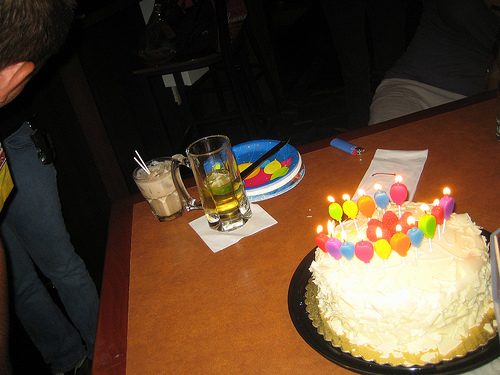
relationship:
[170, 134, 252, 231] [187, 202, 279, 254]
beer on top of napkin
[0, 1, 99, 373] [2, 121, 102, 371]
person wearing jeans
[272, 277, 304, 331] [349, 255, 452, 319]
plate holding cake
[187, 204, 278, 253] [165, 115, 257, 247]
napkin under mug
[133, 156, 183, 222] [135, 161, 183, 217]
cup filled with drink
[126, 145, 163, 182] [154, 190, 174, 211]
straw in glass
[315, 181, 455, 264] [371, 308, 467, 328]
candles on cake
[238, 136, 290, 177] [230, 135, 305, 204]
knife on plates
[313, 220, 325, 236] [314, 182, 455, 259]
flame on candle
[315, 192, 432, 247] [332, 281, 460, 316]
candles on cake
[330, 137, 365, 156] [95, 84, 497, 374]
cigarette lighter on top of table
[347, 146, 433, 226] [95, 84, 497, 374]
paper on top of table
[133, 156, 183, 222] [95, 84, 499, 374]
cup on table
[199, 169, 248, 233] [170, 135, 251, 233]
beer in glass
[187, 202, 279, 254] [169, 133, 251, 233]
napkin under mug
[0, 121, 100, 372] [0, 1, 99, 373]
jeans on person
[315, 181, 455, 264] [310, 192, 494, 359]
candles on top of cake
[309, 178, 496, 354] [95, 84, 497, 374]
cake on table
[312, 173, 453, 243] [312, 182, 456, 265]
flame from fire on candles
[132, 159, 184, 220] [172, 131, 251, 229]
drink in glass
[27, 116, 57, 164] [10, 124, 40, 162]
sunglasses on pocket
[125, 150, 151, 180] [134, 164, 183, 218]
straws cup in cup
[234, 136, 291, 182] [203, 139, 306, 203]
knife on paper plates